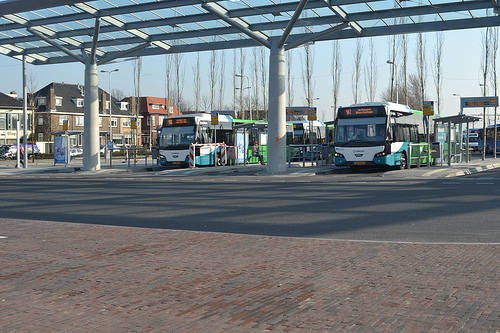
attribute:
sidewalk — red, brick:
[92, 156, 383, 250]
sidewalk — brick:
[18, 226, 480, 331]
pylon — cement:
[265, 41, 287, 176]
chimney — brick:
[49, 89, 59, 111]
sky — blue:
[427, 43, 481, 83]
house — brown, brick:
[33, 74, 142, 174]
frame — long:
[1, 0, 498, 180]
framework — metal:
[0, 6, 466, 66]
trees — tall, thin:
[134, 43, 491, 105]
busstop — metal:
[33, 94, 498, 232]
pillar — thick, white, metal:
[81, 60, 101, 173]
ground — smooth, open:
[8, 163, 498, 243]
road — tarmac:
[3, 216, 498, 332]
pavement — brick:
[0, 173, 495, 243]